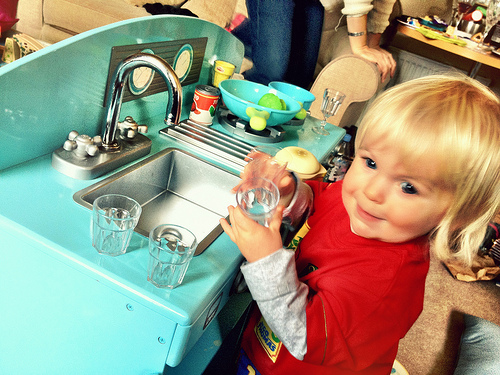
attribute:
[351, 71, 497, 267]
hair — blonde in color, pale brown in color, blonde colored, blonde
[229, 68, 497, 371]
boy — smiling, very young, small, blonde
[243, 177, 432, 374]
tshirt — long sleeved, red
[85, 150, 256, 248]
sink — fake, empty, steel, blue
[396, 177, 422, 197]
eye — open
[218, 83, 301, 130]
bowl — large, plastic, blue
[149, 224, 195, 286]
glass — for drinking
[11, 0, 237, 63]
love seat — tan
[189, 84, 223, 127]
can of vegetables — fake, red, tomato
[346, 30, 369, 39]
bracelet — fashionable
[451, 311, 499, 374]
pillow — grey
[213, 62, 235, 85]
cup — yellow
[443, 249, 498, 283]
trash — brown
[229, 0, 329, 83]
jeans — blue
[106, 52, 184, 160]
faucet — curved